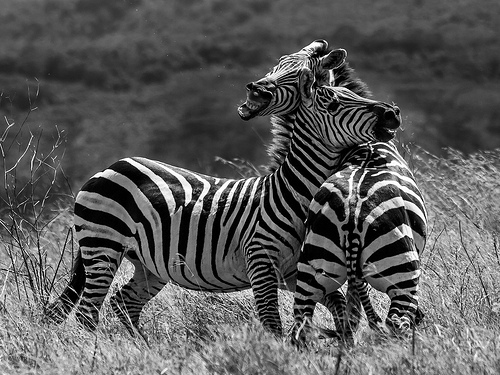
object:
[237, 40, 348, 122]
heads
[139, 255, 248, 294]
stomach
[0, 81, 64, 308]
grass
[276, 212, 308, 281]
chest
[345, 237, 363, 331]
tail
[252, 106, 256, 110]
teeth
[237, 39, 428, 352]
zebra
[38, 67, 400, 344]
zebra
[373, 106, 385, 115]
nostrils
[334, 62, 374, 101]
hair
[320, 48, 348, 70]
ears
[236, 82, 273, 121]
mouth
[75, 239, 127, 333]
legs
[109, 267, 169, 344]
legs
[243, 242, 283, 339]
legs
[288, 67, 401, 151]
head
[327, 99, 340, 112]
eye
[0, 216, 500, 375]
field